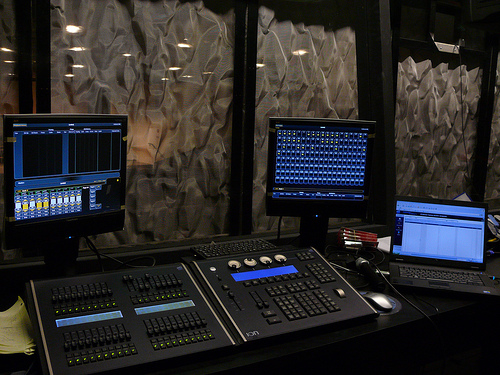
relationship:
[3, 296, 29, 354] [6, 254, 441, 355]
papers on desk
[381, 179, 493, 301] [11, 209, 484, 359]
laptop on desk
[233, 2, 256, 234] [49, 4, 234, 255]
jamb on window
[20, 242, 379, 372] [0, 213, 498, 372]
mixer on counter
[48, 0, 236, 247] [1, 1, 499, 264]
material on wall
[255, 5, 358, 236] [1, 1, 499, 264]
material on wall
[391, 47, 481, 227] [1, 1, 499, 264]
material on wall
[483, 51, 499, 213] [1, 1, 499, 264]
material on wall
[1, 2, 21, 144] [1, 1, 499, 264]
material on wall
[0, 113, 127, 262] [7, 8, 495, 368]
monitor in control room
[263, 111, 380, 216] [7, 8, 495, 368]
monitor in control room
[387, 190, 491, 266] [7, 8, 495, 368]
monitor in control room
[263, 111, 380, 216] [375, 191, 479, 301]
monitor behind monitor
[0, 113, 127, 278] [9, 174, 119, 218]
monitor with icons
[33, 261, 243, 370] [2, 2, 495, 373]
monitor in sound room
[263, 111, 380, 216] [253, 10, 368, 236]
monitor near window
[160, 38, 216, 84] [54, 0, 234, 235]
light reflecting on window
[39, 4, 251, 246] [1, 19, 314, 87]
window with lights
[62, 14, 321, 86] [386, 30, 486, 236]
light reflecting on window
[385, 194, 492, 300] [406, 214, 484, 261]
laptop displaying file list